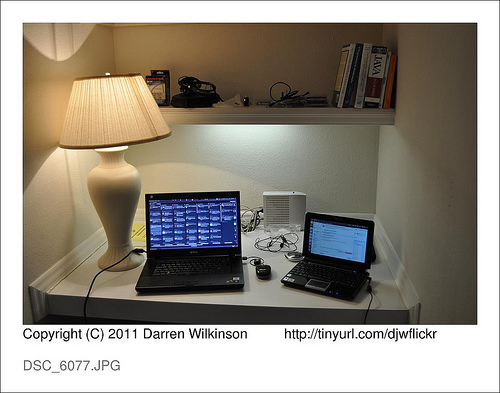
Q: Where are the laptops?
A: On the desk.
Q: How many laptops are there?
A: Two.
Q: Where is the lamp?
A: To the left of the bigger laptop.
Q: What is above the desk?
A: A shelf.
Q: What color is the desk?
A: White.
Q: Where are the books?
A: On the shelf.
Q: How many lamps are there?
A: One.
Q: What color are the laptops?
A: Black.